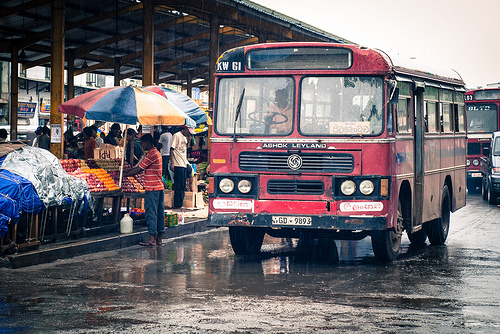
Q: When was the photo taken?
A: Daytime.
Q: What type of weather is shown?
A: Rainy.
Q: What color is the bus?
A: Red.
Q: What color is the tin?
A: Silver.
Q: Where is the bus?
A: Street.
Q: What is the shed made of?
A: Wood.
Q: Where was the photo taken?
A: On the street near the market.